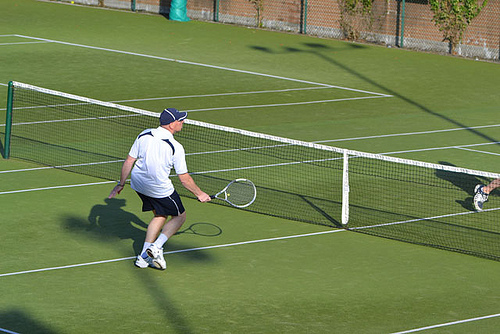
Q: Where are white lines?
A: On the court.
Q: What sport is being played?
A: Tennis.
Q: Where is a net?
A: Between two players.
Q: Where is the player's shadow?
A: On the court.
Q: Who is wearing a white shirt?
A: Tennis player.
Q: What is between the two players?
A: A net.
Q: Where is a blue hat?
A: On player's head.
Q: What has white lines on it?
A: Tennis court.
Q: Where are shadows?
A: On the court.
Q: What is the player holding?
A: Racket.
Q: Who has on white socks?
A: The man.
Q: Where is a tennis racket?
A: In man's hand.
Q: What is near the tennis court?
A: The brick wall.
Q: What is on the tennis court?
A: The tennis net.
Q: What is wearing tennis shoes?
A: The man.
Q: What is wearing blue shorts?
A: The man.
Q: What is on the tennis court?
A: White lines.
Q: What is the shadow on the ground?
A: The man.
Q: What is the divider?
A: A net.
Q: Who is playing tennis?
A: People.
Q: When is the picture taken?
A: Daytime.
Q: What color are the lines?
A: White.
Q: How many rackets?
A: One.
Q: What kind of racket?
A: A tennis racket.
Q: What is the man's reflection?
A: A shadow.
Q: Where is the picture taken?
A: At the court.